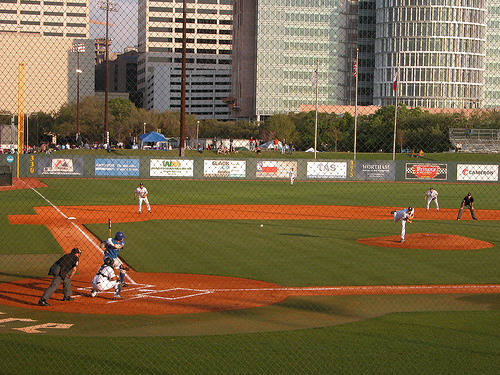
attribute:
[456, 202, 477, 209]
hands —  man's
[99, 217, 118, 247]
bat — for baseball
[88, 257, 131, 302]
catcher — for  baseball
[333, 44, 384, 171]
pole — tall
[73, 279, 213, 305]
white lines —  White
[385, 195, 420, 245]
pitcher — for  baseball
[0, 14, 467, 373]
field — for baseball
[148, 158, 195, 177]
banner — for  baseball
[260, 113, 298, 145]
tree — green, large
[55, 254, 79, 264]
shirt —  umpire's,  black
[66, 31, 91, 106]
pole —  light,  tall,  long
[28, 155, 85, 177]
banner — for  baseball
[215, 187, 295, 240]
baseball — in air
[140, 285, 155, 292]
home plate — for  home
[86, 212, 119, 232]
bat — for baseball 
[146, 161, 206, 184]
banner — for  baseball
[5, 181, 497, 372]
field — for  baseball , for base ball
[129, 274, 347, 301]
lines —  of chalk,  white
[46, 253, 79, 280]
vest —  black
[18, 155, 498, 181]
wall — of outfield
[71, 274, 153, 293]
box —  batter's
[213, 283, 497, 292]
line —  white,   long 